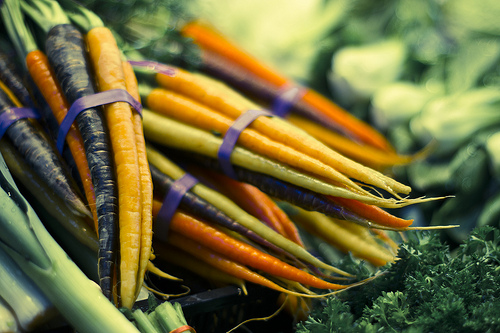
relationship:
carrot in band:
[141, 107, 380, 206] [218, 108, 272, 179]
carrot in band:
[141, 107, 380, 206] [203, 95, 275, 163]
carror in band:
[125, 20, 372, 150] [262, 79, 299, 113]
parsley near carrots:
[294, 220, 496, 330] [5, 15, 417, 298]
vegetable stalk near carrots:
[0, 167, 135, 329] [5, 15, 417, 298]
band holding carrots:
[218, 108, 272, 183] [138, 55, 409, 247]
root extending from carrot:
[117, 34, 452, 318] [129, 71, 401, 289]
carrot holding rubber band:
[141, 107, 380, 206] [271, 86, 301, 115]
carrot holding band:
[154, 65, 409, 199] [218, 108, 272, 179]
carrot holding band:
[191, 70, 410, 193] [218, 108, 272, 179]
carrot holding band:
[141, 107, 380, 206] [218, 108, 272, 179]